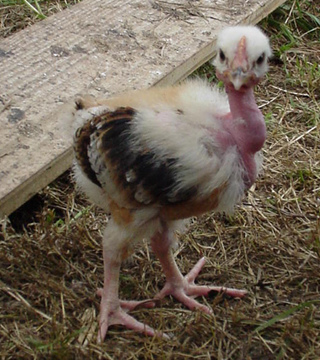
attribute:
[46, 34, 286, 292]
hen — young, baby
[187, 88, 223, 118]
feathers — white, brown, black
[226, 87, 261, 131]
neck — long, red, pink, featherless, bare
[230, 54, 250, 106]
beak — short, sharp, white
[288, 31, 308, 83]
dry grass — brown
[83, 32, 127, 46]
board — dirty, brown, wooden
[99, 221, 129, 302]
leg — pink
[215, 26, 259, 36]
fluff — white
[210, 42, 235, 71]
eye — black, dark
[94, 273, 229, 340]
feet — pink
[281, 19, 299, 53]
grass — green